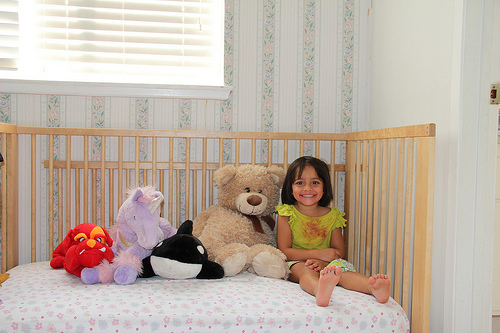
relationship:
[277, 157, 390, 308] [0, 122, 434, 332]
girl sitting on bed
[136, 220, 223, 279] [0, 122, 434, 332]
whale on top of bed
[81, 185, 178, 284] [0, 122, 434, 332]
unicorn on top of bed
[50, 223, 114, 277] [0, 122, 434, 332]
bulldog on top of bed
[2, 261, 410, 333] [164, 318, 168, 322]
mattress has flower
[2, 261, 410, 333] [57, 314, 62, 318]
mattress has flower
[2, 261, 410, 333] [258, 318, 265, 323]
mattress has flower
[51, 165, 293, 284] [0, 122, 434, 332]
stuffed animals are on top of bed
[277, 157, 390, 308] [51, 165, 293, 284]
girl next to stuffed animals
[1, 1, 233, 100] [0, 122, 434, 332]
window over bed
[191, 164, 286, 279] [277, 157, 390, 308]
teddy bear next to girl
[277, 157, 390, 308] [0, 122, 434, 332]
girl inside bed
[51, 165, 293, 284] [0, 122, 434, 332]
stuffed animals are inside of bed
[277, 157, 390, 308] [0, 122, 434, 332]
girl sitting in bed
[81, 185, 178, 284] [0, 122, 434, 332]
unicorn inside of bed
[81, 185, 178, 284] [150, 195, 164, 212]
unicorn has horn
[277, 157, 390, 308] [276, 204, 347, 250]
girl wearing blouse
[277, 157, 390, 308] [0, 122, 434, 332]
girl inside of bed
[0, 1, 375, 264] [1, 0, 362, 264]
wallpaper on top of wall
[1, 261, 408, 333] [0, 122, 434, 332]
sheet on top of bed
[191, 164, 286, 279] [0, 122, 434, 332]
teddy bear on top of bed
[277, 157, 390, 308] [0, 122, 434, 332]
girl on top of bed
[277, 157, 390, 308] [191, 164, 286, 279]
girl next to teddy bear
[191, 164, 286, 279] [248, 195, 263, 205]
teddy bear has brown nose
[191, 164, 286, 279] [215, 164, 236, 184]
teddy bear has ear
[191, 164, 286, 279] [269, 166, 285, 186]
teddy bear has ear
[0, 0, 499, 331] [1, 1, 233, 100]
room has window